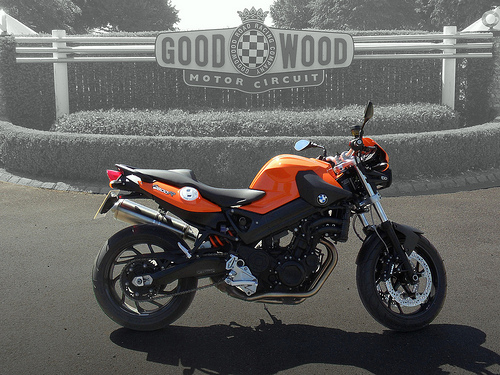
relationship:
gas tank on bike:
[178, 184, 200, 202] [91, 100, 448, 331]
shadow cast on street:
[110, 304, 500, 375] [11, 159, 494, 374]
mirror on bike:
[295, 140, 312, 150] [91, 100, 448, 331]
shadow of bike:
[105, 313, 496, 371] [91, 100, 448, 331]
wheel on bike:
[354, 217, 452, 332] [91, 100, 448, 331]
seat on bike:
[187, 167, 270, 213] [91, 100, 448, 331]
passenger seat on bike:
[116, 160, 206, 191] [91, 100, 448, 331]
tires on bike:
[100, 215, 437, 333] [101, 112, 402, 295]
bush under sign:
[42, 94, 459, 137] [151, 5, 356, 92]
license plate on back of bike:
[88, 184, 120, 225] [91, 95, 451, 334]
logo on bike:
[314, 192, 332, 206] [91, 95, 451, 334]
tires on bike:
[91, 223, 198, 332] [91, 100, 448, 331]